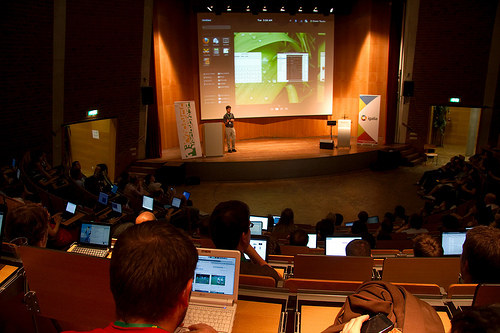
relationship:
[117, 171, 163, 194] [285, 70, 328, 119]
people watching presentation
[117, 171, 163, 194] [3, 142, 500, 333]
people in classroom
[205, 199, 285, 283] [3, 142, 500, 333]
person in classroom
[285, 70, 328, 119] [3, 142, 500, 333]
presentation in classroom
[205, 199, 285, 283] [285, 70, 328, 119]
person a presentation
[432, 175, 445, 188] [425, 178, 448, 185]
holding a phone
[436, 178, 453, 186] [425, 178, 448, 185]
hand holding phone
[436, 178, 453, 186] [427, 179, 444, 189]
hand holding cell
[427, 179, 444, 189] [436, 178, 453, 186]
cell in hand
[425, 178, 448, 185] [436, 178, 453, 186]
phone in hand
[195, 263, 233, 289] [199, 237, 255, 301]
images on computer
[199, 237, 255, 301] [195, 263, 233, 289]
computer displayed images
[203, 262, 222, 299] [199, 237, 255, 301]
displayed on computer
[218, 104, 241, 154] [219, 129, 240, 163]
man on stage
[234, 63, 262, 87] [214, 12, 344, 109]
text on screen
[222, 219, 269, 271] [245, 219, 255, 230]
person wearing glasses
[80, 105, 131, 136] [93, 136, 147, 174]
exit to area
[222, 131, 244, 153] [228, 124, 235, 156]
article of clothing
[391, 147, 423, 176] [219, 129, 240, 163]
steps to stage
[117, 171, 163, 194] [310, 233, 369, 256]
people have computers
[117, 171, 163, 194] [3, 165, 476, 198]
people in classroom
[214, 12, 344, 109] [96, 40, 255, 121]
screen on wall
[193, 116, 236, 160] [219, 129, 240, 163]
podium on stage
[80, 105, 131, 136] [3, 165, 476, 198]
exit to classroom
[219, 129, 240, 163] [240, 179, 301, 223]
stage in front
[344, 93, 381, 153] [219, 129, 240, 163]
sign on stage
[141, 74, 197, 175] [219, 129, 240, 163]
side of stage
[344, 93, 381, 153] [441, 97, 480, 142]
sign above door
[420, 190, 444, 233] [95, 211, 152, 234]
stairs on right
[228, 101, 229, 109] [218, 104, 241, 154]
hair of man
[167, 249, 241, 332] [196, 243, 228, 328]
monitor of laptop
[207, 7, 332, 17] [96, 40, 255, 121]
projector on wall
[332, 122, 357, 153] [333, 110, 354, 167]
part of board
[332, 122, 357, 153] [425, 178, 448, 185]
part of phone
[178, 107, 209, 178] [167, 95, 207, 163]
standing white advertisement panel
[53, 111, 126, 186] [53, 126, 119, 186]
entry at entry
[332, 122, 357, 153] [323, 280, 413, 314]
part of jacket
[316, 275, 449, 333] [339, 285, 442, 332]
coat brown coat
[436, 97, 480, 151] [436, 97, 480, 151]
door way door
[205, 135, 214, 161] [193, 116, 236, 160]
white rectangular podium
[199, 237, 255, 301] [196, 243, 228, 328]
bright white laptop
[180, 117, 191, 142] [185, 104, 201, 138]
yellow and green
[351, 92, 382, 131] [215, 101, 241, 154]
colored logo man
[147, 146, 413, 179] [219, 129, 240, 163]
semi round stage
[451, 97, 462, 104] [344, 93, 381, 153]
lit up sign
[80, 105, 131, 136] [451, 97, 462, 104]
exit sign lit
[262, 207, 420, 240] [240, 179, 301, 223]
seating in front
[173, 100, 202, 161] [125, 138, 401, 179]
advertisement panel on stage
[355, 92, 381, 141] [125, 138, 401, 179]
advertisement panel on stage